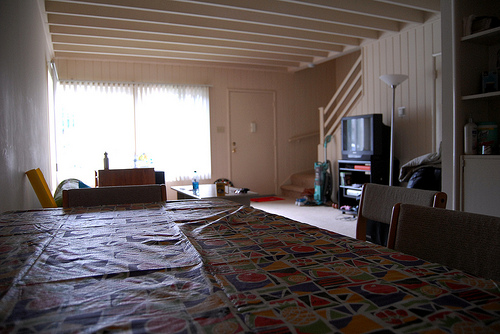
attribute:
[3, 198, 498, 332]
tablecloth — patterend, colorful, patterned, mulit-colored, festive, plastic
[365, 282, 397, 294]
pattern — circular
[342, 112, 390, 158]
tv — old, dark, small, off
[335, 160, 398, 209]
stand — black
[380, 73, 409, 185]
lamp — white, standing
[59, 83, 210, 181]
window — shining, white, sunlit, covered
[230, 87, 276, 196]
door — rectangular, tan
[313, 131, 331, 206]
vaccum — blue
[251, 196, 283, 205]
floormat — red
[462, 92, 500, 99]
shelf — dark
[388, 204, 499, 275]
chair — wooden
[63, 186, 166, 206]
chair — wooden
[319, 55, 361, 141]
bannister — white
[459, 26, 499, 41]
shelf — white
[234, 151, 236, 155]
knob — gold